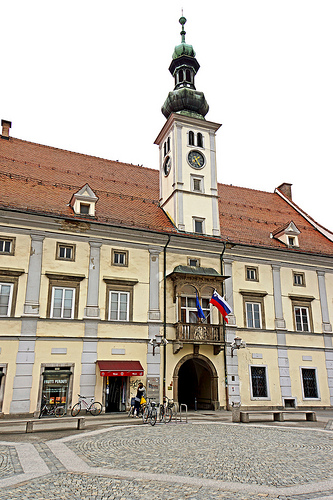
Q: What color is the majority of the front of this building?
A: Yellow.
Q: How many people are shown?
A: One.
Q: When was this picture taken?
A: Day time.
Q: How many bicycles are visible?
A: Five.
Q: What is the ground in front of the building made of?
A: Stone.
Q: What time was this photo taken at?
A: 2:25.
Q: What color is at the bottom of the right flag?
A: Red.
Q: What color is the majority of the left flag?
A: Blue.